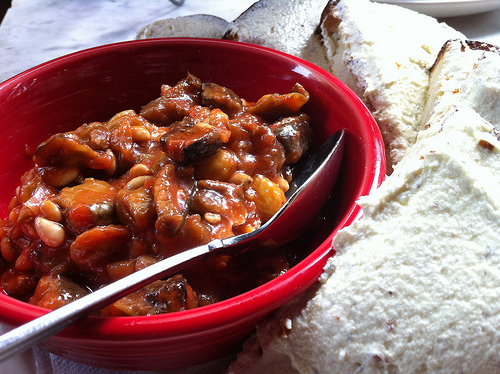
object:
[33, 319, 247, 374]
side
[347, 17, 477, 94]
bread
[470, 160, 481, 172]
ground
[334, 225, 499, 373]
bread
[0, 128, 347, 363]
spoon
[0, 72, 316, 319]
chili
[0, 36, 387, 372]
bowl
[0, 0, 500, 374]
table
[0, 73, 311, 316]
food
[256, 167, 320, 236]
edge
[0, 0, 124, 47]
cloth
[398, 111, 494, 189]
bread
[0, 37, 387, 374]
dish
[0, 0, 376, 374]
stuff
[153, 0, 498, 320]
stuff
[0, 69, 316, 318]
vegetables